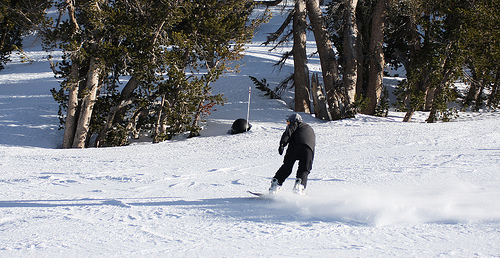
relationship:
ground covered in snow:
[5, 33, 494, 256] [348, 166, 431, 230]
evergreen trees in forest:
[71, 12, 126, 152] [56, 11, 327, 141]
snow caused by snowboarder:
[0, 0, 498, 258] [273, 107, 323, 195]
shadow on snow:
[0, 198, 272, 217] [7, 143, 257, 250]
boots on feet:
[266, 174, 311, 199] [262, 176, 309, 206]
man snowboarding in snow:
[271, 114, 316, 191] [1, 1, 497, 255]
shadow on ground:
[1, 195, 262, 215] [0, 62, 496, 252]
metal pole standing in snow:
[244, 85, 254, 130] [1, 1, 497, 255]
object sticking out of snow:
[220, 117, 254, 136] [3, 117, 469, 256]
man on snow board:
[248, 89, 327, 214] [228, 153, 320, 215]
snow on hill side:
[0, 0, 498, 258] [42, 16, 372, 186]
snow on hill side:
[0, 0, 498, 258] [2, 31, 497, 253]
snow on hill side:
[1, 1, 497, 255] [12, 53, 484, 250]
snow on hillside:
[0, 0, 498, 258] [2, 56, 483, 255]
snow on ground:
[0, 0, 498, 258] [0, 0, 496, 255]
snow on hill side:
[0, 0, 498, 258] [89, 124, 219, 198]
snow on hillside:
[1, 1, 497, 255] [0, 118, 485, 256]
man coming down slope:
[271, 114, 316, 191] [0, 111, 499, 256]